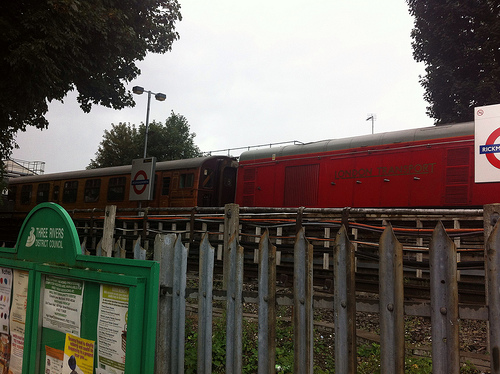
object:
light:
[132, 85, 144, 94]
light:
[155, 93, 167, 101]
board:
[0, 199, 159, 373]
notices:
[41, 274, 83, 338]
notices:
[95, 282, 129, 372]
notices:
[44, 346, 64, 373]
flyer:
[60, 331, 97, 374]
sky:
[0, 0, 434, 171]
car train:
[235, 122, 500, 210]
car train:
[3, 153, 237, 226]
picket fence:
[0, 207, 498, 369]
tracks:
[2, 219, 494, 299]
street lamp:
[132, 85, 166, 157]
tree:
[83, 110, 202, 171]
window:
[106, 176, 127, 202]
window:
[83, 178, 102, 203]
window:
[62, 181, 79, 204]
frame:
[2, 198, 165, 374]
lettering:
[48, 227, 52, 239]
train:
[7, 122, 499, 224]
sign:
[472, 104, 497, 185]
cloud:
[0, 1, 423, 175]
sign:
[25, 225, 64, 249]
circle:
[133, 170, 147, 195]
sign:
[129, 157, 157, 201]